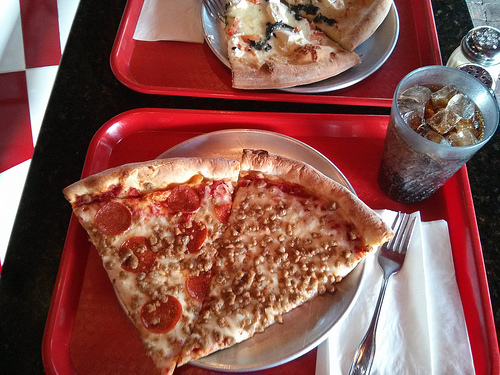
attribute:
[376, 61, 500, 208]
drink — soft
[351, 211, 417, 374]
fork — silver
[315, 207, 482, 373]
napkin — clean, white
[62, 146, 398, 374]
slices — different, thin, pizza, big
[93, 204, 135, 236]
pepperoni — one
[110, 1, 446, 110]
tray — red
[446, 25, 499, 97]
shakers — salt, cheese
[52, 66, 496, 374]
meal — nice, full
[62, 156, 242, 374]
pizza — slices, pepperoni, brown, red, crumbles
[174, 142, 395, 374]
slice — large, pizza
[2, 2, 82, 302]
linoluem — checkered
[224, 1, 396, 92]
pizza — spinach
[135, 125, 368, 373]
plate — silver